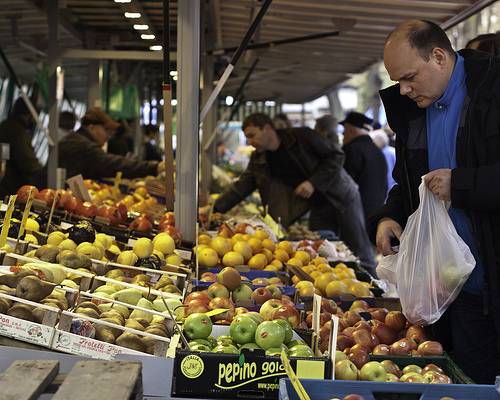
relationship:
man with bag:
[366, 17, 499, 382] [376, 176, 477, 328]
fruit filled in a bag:
[394, 261, 466, 327] [376, 176, 477, 328]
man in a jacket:
[213, 112, 380, 283] [212, 126, 360, 227]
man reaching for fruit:
[213, 112, 380, 283] [198, 214, 211, 225]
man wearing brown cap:
[59, 106, 165, 179] [82, 107, 122, 133]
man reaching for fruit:
[59, 106, 165, 179] [158, 171, 176, 189]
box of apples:
[175, 229, 500, 399] [335, 351, 452, 385]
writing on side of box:
[176, 351, 328, 396] [175, 229, 500, 399]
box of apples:
[175, 229, 500, 399] [183, 309, 313, 357]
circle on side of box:
[179, 355, 204, 378] [175, 229, 500, 399]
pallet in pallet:
[1, 358, 145, 399] [1, 359, 144, 399]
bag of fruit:
[376, 176, 477, 328] [394, 261, 466, 327]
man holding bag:
[366, 17, 499, 382] [376, 176, 477, 328]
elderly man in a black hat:
[337, 112, 389, 217] [338, 111, 376, 133]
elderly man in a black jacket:
[337, 112, 389, 217] [341, 134, 388, 210]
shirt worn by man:
[423, 50, 485, 294] [366, 17, 499, 382]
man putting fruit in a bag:
[366, 17, 499, 382] [376, 176, 477, 328]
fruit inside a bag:
[394, 261, 466, 327] [376, 176, 477, 328]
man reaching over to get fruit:
[213, 112, 380, 283] [198, 214, 211, 225]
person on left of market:
[59, 106, 165, 179] [1, 1, 178, 398]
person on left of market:
[1, 96, 48, 187] [1, 1, 178, 398]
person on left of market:
[142, 123, 167, 161] [1, 1, 178, 398]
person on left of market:
[109, 118, 132, 153] [1, 1, 178, 398]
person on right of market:
[213, 112, 380, 283] [203, 2, 499, 321]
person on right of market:
[339, 110, 388, 211] [203, 2, 499, 321]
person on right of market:
[312, 115, 340, 148] [203, 2, 499, 321]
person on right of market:
[366, 17, 499, 382] [1, 1, 178, 398]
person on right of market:
[273, 113, 293, 132] [203, 2, 499, 321]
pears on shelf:
[0, 267, 182, 362] [1, 267, 177, 360]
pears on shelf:
[3, 270, 168, 354] [1, 267, 177, 360]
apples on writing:
[185, 266, 454, 384] [171, 351, 333, 399]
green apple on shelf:
[230, 315, 255, 343] [1, 267, 177, 360]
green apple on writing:
[230, 315, 255, 343] [171, 351, 333, 399]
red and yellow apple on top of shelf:
[183, 266, 387, 382] [144, 356, 498, 399]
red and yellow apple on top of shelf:
[359, 362, 389, 385] [144, 356, 498, 399]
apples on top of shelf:
[335, 351, 452, 385] [144, 356, 498, 399]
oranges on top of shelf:
[196, 229, 374, 298] [142, 228, 386, 399]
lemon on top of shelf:
[23, 219, 183, 266] [1, 219, 172, 399]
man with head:
[366, 17, 499, 382] [383, 19, 454, 108]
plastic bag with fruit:
[376, 176, 477, 328] [394, 261, 466, 327]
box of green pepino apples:
[175, 229, 500, 399] [183, 309, 313, 357]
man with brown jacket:
[213, 112, 380, 283] [212, 126, 360, 227]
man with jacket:
[59, 106, 165, 179] [38, 124, 160, 187]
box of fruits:
[175, 229, 500, 399] [335, 351, 452, 385]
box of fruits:
[175, 229, 500, 399] [183, 309, 313, 357]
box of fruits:
[1, 275, 177, 363] [3, 270, 168, 354]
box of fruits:
[175, 229, 500, 399] [200, 271, 287, 285]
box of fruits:
[293, 270, 386, 296] [298, 261, 384, 298]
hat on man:
[82, 107, 122, 133] [59, 106, 165, 179]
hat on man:
[338, 111, 376, 133] [337, 112, 389, 217]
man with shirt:
[366, 17, 499, 382] [423, 50, 485, 294]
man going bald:
[366, 17, 499, 382] [385, 18, 430, 46]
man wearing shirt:
[366, 17, 499, 382] [423, 50, 485, 294]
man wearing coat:
[366, 17, 499, 382] [365, 49, 497, 318]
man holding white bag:
[366, 17, 499, 382] [376, 176, 477, 328]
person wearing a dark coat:
[339, 110, 388, 211] [341, 134, 388, 210]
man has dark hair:
[366, 17, 499, 382] [412, 18, 455, 64]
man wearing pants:
[366, 17, 499, 382] [428, 292, 499, 383]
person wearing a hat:
[339, 110, 388, 211] [338, 111, 376, 133]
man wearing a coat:
[366, 17, 499, 382] [365, 49, 497, 318]